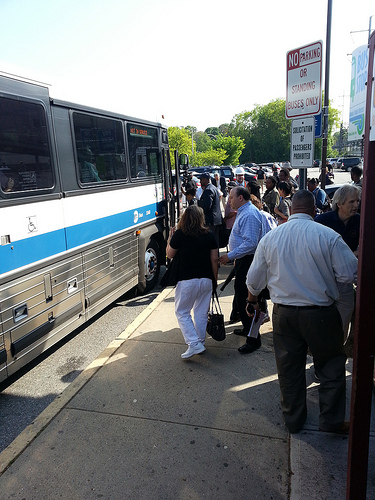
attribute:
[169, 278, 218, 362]
pants — white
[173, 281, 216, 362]
pants — white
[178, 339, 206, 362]
shoes — white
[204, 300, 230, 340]
bag — black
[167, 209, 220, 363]
short woman — short 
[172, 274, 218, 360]
white pants — white 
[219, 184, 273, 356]
man — old , fat  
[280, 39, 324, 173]
sign — tall 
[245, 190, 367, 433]
guy — short , fat 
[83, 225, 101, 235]
blue stripe — BLUE 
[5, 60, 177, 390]
bus — white , blue 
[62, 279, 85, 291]
light — YELLOW 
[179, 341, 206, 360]
shoes — WHITE 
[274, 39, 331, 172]
sign — NO PARKING  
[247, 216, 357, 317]
shirt — CHECKER  